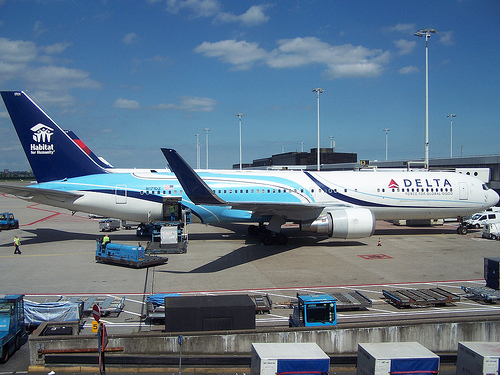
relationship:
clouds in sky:
[202, 31, 393, 79] [0, 0, 498, 172]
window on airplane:
[264, 186, 273, 199] [4, 79, 496, 284]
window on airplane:
[276, 187, 283, 194] [4, 79, 496, 284]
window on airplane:
[340, 186, 351, 196] [4, 79, 496, 284]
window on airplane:
[307, 186, 318, 196] [4, 79, 496, 284]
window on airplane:
[298, 186, 307, 199] [4, 79, 496, 284]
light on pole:
[311, 85, 323, 96] [315, 91, 320, 172]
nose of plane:
[484, 186, 499, 219] [3, 87, 498, 239]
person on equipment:
[2, 229, 34, 256] [95, 243, 168, 269]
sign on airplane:
[27, 120, 57, 155] [0, 88, 499, 243]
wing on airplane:
[159, 148, 325, 233] [1, 73, 493, 244]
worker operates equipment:
[102, 227, 112, 248] [96, 241, 150, 270]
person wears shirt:
[13, 235, 22, 254] [10, 238, 21, 248]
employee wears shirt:
[99, 229, 109, 249] [101, 237, 110, 246]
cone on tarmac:
[375, 230, 400, 264] [324, 230, 422, 269]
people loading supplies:
[170, 205, 175, 218] [155, 222, 179, 251]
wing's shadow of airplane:
[155, 242, 303, 273] [5, 74, 499, 264]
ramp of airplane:
[145, 194, 192, 256] [5, 74, 499, 264]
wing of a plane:
[147, 158, 256, 238] [15, 62, 488, 263]